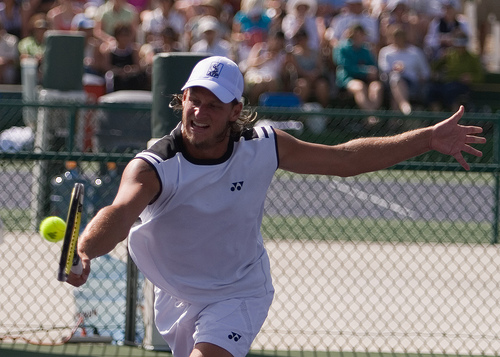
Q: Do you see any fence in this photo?
A: Yes, there is a fence.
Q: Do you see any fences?
A: Yes, there is a fence.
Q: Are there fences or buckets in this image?
A: Yes, there is a fence.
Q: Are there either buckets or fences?
A: Yes, there is a fence.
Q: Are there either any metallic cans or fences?
A: Yes, there is a metal fence.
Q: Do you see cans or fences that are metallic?
A: Yes, the fence is metallic.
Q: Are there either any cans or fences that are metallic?
A: Yes, the fence is metallic.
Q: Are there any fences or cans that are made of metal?
A: Yes, the fence is made of metal.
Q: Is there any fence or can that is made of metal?
A: Yes, the fence is made of metal.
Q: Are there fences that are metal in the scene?
A: Yes, there is a metal fence.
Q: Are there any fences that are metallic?
A: Yes, there is a fence that is metallic.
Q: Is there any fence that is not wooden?
A: Yes, there is a metallic fence.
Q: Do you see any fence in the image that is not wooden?
A: Yes, there is a metallic fence.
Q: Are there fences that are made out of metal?
A: Yes, there is a fence that is made of metal.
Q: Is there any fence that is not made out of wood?
A: Yes, there is a fence that is made of metal.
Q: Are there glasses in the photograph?
A: No, there are no glasses.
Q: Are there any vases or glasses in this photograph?
A: No, there are no glasses or vases.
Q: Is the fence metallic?
A: Yes, the fence is metallic.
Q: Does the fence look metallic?
A: Yes, the fence is metallic.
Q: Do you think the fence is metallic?
A: Yes, the fence is metallic.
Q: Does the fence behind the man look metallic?
A: Yes, the fence is metallic.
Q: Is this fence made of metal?
A: Yes, the fence is made of metal.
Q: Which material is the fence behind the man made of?
A: The fence is made of metal.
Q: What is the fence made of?
A: The fence is made of metal.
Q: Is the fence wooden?
A: No, the fence is metallic.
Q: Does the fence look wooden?
A: No, the fence is metallic.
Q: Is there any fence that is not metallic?
A: No, there is a fence but it is metallic.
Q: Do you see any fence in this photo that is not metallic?
A: No, there is a fence but it is metallic.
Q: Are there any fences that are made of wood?
A: No, there is a fence but it is made of metal.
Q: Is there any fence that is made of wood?
A: No, there is a fence but it is made of metal.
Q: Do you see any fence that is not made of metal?
A: No, there is a fence but it is made of metal.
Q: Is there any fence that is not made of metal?
A: No, there is a fence but it is made of metal.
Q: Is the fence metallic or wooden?
A: The fence is metallic.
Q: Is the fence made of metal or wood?
A: The fence is made of metal.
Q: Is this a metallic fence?
A: Yes, this is a metallic fence.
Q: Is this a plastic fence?
A: No, this is a metallic fence.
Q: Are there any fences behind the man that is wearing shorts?
A: Yes, there is a fence behind the man.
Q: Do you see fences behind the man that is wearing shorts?
A: Yes, there is a fence behind the man.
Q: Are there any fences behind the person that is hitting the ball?
A: Yes, there is a fence behind the man.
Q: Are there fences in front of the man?
A: No, the fence is behind the man.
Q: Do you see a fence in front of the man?
A: No, the fence is behind the man.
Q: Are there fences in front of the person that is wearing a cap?
A: No, the fence is behind the man.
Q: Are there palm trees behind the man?
A: No, there is a fence behind the man.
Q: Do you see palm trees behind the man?
A: No, there is a fence behind the man.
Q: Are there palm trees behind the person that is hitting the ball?
A: No, there is a fence behind the man.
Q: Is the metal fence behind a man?
A: Yes, the fence is behind a man.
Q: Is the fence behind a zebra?
A: No, the fence is behind a man.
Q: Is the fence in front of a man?
A: No, the fence is behind a man.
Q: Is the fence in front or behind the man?
A: The fence is behind the man.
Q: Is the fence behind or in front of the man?
A: The fence is behind the man.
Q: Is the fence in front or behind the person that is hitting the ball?
A: The fence is behind the man.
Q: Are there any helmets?
A: No, there are no helmets.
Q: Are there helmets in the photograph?
A: No, there are no helmets.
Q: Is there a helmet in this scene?
A: No, there are no helmets.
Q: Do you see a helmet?
A: No, there are no helmets.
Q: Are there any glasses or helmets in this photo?
A: No, there are no helmets or glasses.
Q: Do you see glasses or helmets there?
A: No, there are no helmets or glasses.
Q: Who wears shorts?
A: The man wears shorts.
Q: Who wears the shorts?
A: The man wears shorts.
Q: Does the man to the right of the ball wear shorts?
A: Yes, the man wears shorts.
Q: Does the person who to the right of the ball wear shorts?
A: Yes, the man wears shorts.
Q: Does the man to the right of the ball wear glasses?
A: No, the man wears shorts.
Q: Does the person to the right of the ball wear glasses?
A: No, the man wears shorts.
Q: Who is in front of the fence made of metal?
A: The man is in front of the fence.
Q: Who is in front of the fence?
A: The man is in front of the fence.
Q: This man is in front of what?
A: The man is in front of the fence.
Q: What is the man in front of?
A: The man is in front of the fence.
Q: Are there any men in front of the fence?
A: Yes, there is a man in front of the fence.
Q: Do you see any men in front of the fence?
A: Yes, there is a man in front of the fence.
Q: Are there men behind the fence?
A: No, the man is in front of the fence.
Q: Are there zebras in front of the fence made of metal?
A: No, there is a man in front of the fence.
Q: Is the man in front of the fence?
A: Yes, the man is in front of the fence.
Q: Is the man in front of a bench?
A: No, the man is in front of the fence.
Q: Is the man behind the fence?
A: No, the man is in front of the fence.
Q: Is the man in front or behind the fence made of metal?
A: The man is in front of the fence.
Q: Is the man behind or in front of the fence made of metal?
A: The man is in front of the fence.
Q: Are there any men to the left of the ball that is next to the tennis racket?
A: No, the man is to the right of the ball.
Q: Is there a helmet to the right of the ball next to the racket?
A: No, there is a man to the right of the ball.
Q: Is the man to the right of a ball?
A: Yes, the man is to the right of a ball.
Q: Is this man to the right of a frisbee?
A: No, the man is to the right of a ball.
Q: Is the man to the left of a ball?
A: No, the man is to the right of a ball.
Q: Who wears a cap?
A: The man wears a cap.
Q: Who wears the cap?
A: The man wears a cap.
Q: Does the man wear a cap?
A: Yes, the man wears a cap.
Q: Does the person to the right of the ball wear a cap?
A: Yes, the man wears a cap.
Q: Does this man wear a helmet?
A: No, the man wears a cap.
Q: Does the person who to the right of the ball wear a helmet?
A: No, the man wears a cap.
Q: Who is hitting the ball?
A: The man is hitting the ball.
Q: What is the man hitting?
A: The man is hitting the ball.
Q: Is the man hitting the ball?
A: Yes, the man is hitting the ball.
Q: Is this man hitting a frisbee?
A: No, the man is hitting the ball.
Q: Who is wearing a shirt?
A: The man is wearing a shirt.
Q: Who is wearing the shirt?
A: The man is wearing a shirt.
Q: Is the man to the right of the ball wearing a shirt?
A: Yes, the man is wearing a shirt.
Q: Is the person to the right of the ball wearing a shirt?
A: Yes, the man is wearing a shirt.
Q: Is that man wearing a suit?
A: No, the man is wearing a shirt.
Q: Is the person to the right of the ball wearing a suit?
A: No, the man is wearing a shirt.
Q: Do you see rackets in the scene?
A: Yes, there is a racket.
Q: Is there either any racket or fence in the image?
A: Yes, there is a racket.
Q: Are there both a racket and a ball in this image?
A: Yes, there are both a racket and a ball.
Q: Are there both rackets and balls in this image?
A: Yes, there are both a racket and a ball.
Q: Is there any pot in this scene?
A: No, there are no pots.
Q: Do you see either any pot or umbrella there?
A: No, there are no pots or umbrellas.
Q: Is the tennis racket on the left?
A: Yes, the tennis racket is on the left of the image.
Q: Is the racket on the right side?
A: No, the racket is on the left of the image.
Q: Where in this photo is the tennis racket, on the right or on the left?
A: The tennis racket is on the left of the image.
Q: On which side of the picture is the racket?
A: The racket is on the left of the image.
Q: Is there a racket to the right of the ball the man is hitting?
A: Yes, there is a racket to the right of the ball.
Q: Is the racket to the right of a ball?
A: Yes, the racket is to the right of a ball.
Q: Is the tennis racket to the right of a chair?
A: No, the tennis racket is to the right of a ball.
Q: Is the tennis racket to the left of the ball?
A: No, the tennis racket is to the right of the ball.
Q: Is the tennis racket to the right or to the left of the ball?
A: The tennis racket is to the right of the ball.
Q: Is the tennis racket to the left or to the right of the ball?
A: The tennis racket is to the right of the ball.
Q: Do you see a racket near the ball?
A: Yes, there is a racket near the ball.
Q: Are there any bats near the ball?
A: No, there is a racket near the ball.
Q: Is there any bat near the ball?
A: No, there is a racket near the ball.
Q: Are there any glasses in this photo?
A: No, there are no glasses.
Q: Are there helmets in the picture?
A: No, there are no helmets.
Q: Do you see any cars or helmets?
A: No, there are no helmets or cars.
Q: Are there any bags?
A: No, there are no bags.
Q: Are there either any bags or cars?
A: No, there are no bags or cars.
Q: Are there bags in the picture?
A: No, there are no bags.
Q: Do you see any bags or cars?
A: No, there are no bags or cars.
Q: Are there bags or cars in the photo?
A: No, there are no bags or cars.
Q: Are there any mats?
A: No, there are no mats.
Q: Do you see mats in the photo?
A: No, there are no mats.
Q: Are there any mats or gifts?
A: No, there are no mats or gifts.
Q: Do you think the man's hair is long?
A: Yes, the hair is long.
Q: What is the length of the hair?
A: The hair is long.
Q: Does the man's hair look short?
A: No, the hair is long.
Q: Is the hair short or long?
A: The hair is long.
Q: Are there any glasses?
A: No, there are no glasses.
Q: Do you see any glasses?
A: No, there are no glasses.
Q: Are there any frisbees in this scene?
A: No, there are no frisbees.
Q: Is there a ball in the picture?
A: Yes, there is a ball.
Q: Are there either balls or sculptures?
A: Yes, there is a ball.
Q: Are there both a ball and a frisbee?
A: No, there is a ball but no frisbees.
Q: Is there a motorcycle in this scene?
A: No, there are no motorcycles.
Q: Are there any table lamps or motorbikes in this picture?
A: No, there are no motorbikes or table lamps.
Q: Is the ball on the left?
A: Yes, the ball is on the left of the image.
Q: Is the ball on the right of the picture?
A: No, the ball is on the left of the image.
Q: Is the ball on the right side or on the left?
A: The ball is on the left of the image.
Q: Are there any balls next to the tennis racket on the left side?
A: Yes, there is a ball next to the tennis racket.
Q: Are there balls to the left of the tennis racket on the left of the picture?
A: Yes, there is a ball to the left of the tennis racket.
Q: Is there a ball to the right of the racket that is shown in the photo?
A: No, the ball is to the left of the racket.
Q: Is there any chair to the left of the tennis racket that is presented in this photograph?
A: No, there is a ball to the left of the tennis racket.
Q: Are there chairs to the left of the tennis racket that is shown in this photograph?
A: No, there is a ball to the left of the tennis racket.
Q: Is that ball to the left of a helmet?
A: No, the ball is to the left of a racket.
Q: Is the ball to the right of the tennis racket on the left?
A: No, the ball is to the left of the tennis racket.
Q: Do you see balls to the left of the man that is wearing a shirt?
A: Yes, there is a ball to the left of the man.